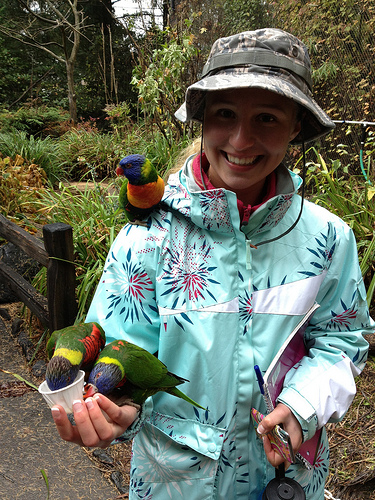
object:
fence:
[0, 213, 78, 341]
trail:
[0, 318, 122, 499]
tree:
[0, 0, 91, 121]